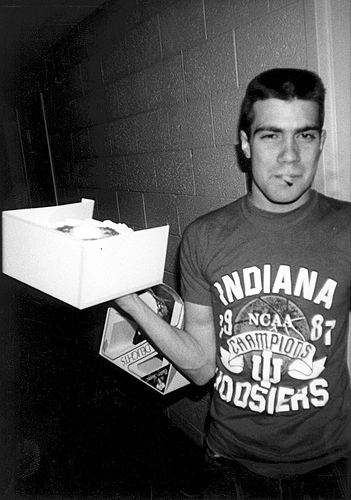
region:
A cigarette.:
[282, 173, 297, 187]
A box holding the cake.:
[1, 198, 175, 306]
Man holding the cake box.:
[10, 61, 349, 341]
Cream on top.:
[74, 221, 100, 238]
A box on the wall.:
[109, 306, 198, 395]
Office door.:
[13, 98, 62, 203]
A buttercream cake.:
[46, 217, 141, 242]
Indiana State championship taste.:
[208, 263, 340, 416]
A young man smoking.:
[242, 64, 327, 204]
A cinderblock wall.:
[47, 49, 221, 181]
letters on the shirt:
[210, 273, 337, 441]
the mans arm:
[166, 326, 198, 365]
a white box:
[86, 245, 160, 280]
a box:
[84, 249, 167, 280]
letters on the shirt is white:
[211, 268, 334, 302]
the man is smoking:
[283, 177, 294, 187]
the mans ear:
[235, 130, 255, 160]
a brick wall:
[85, 46, 201, 140]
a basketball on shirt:
[238, 302, 258, 317]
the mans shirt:
[232, 427, 335, 456]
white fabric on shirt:
[270, 393, 276, 409]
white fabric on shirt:
[255, 392, 262, 416]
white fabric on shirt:
[241, 386, 249, 407]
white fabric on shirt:
[298, 389, 308, 409]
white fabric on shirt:
[316, 384, 318, 403]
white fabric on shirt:
[298, 370, 314, 373]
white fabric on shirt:
[266, 368, 276, 381]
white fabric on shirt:
[251, 316, 271, 320]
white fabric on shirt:
[320, 295, 329, 302]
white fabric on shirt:
[314, 316, 322, 339]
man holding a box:
[15, 196, 170, 319]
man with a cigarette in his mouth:
[274, 170, 303, 191]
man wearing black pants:
[191, 444, 332, 495]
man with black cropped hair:
[227, 57, 339, 135]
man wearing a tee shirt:
[194, 213, 348, 479]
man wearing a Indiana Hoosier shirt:
[189, 247, 335, 425]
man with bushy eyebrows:
[247, 121, 333, 153]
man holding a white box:
[9, 189, 179, 312]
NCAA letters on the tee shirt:
[245, 310, 291, 325]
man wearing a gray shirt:
[174, 201, 321, 289]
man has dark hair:
[231, 53, 307, 126]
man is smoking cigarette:
[279, 159, 309, 195]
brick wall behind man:
[126, 66, 236, 208]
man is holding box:
[38, 197, 160, 289]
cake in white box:
[14, 188, 169, 307]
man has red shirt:
[166, 199, 338, 455]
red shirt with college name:
[204, 203, 334, 452]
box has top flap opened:
[105, 248, 209, 396]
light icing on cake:
[69, 213, 128, 257]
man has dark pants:
[186, 420, 336, 495]